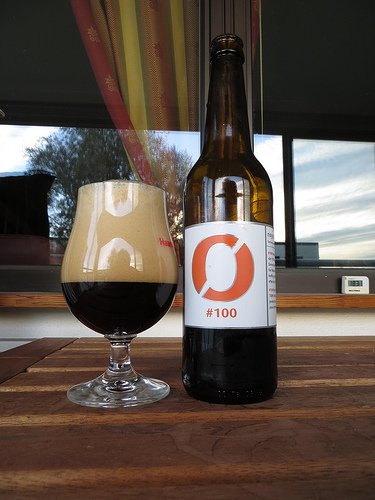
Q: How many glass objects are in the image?
A: Two.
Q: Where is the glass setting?
A: On a table.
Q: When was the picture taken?
A: During daylight.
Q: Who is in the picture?
A: No one.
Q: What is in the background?
A: A tree.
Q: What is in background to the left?
A: A building.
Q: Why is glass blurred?
A: Reflections.